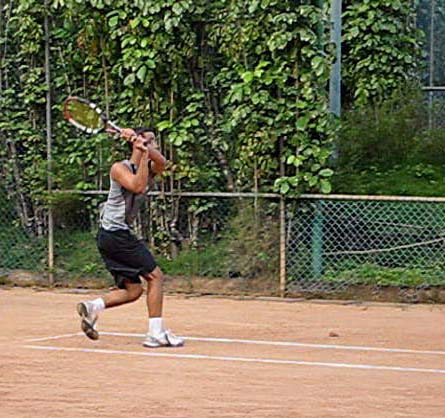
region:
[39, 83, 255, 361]
man is holding a tennis racket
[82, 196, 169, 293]
man's shorts are black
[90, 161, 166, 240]
man's shirt is gray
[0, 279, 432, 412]
tennis court is orange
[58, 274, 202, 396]
tennis player's shoes are white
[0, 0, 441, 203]
tree's leaves are green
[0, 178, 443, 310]
metal fence in front of man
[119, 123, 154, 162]
man's hair is black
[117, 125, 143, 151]
man is wearing a watch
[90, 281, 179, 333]
man's socks are white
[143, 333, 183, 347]
a shoe on a foot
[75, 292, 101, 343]
a shoe on a foot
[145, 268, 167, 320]
a leg of a person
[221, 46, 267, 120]
leaves of a tree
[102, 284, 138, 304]
leg of a man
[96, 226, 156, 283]
a black pair of shorts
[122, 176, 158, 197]
an elbow of a person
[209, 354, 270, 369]
white stripe on the ground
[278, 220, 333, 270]
a pole and chain length fence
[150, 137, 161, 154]
a nose on a face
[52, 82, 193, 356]
a man playing tennis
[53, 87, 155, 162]
a black and white tennis racket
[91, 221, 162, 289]
a pair of black board shorts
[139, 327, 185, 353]
a right white and black tennis shoe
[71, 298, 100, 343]
a left white and black tennis shoe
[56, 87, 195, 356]
a tennis player swinging a racket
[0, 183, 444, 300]
a metal chainlink fence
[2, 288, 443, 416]
a tennis court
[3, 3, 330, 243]
a grouping of tall trees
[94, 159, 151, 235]
a men's grey and black tank top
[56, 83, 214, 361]
A tennis player playing.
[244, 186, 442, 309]
A fence in the background.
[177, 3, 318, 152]
A lot of vegetation in the background.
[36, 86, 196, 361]
A player holding their racket.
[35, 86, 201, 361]
He is holding the racket with two hands.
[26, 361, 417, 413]
The tennis court is brown.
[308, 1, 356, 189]
A pole is among the plants.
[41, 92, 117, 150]
The tennis racket is yellow.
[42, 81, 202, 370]
The player is wearing black and grey.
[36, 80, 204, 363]
The player is wearing tennis shoes.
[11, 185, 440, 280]
a chain link fense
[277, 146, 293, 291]
a pole supporting a fence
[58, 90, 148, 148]
two hands holding a racquet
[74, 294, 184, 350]
white tennis shoes on a man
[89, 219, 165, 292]
black shorts on a man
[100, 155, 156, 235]
a grey sleeveless shirt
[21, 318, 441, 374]
white lines on a tennis court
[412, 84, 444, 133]
a fence in the background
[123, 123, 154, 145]
black hair on a man's head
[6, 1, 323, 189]
trees crowding a fence